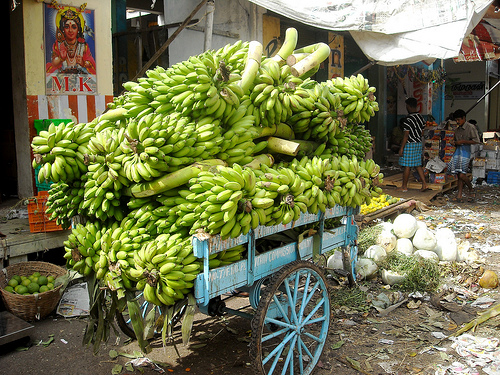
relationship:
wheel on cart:
[248, 261, 333, 374] [115, 196, 361, 374]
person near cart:
[395, 96, 431, 195] [115, 196, 361, 374]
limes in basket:
[7, 272, 57, 292] [3, 259, 69, 319]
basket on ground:
[3, 259, 69, 319] [3, 190, 500, 370]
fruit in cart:
[33, 28, 368, 297] [115, 196, 361, 374]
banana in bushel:
[51, 146, 67, 154] [32, 121, 93, 182]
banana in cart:
[51, 146, 67, 154] [115, 196, 361, 374]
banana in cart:
[222, 201, 236, 210] [115, 196, 361, 374]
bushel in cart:
[32, 121, 93, 182] [115, 196, 361, 374]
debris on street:
[435, 268, 496, 330] [147, 176, 498, 373]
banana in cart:
[258, 74, 275, 86] [115, 196, 361, 374]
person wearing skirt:
[395, 96, 431, 195] [399, 142, 423, 167]